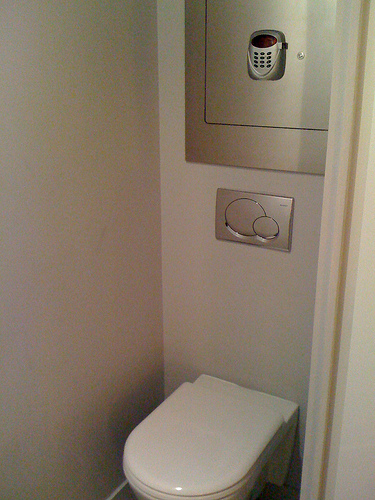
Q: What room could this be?
A: It is a bathroom.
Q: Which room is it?
A: It is a bathroom.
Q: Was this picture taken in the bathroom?
A: Yes, it was taken in the bathroom.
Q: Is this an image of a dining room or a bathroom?
A: It is showing a bathroom.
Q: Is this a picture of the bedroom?
A: No, the picture is showing the bathroom.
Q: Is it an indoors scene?
A: Yes, it is indoors.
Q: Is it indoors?
A: Yes, it is indoors.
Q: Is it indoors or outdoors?
A: It is indoors.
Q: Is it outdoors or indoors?
A: It is indoors.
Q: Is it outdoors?
A: No, it is indoors.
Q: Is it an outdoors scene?
A: No, it is indoors.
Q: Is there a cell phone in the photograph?
A: Yes, there is a cell phone.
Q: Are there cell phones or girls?
A: Yes, there is a cell phone.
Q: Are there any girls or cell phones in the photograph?
A: Yes, there is a cell phone.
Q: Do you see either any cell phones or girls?
A: Yes, there is a cell phone.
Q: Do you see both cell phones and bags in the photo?
A: No, there is a cell phone but no bags.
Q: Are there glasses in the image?
A: No, there are no glasses.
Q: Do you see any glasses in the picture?
A: No, there are no glasses.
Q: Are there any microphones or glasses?
A: No, there are no glasses or microphones.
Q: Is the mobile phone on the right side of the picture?
A: Yes, the mobile phone is on the right of the image.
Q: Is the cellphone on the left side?
A: No, the cellphone is on the right of the image.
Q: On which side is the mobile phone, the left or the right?
A: The mobile phone is on the right of the image.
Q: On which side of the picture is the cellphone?
A: The cellphone is on the right of the image.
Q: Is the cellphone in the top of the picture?
A: Yes, the cellphone is in the top of the image.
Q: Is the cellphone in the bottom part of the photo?
A: No, the cellphone is in the top of the image.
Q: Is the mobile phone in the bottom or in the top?
A: The mobile phone is in the top of the image.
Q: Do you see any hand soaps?
A: No, there are no hand soaps.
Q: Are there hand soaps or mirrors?
A: No, there are no hand soaps or mirrors.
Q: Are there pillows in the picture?
A: No, there are no pillows.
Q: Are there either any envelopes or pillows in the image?
A: No, there are no pillows or envelopes.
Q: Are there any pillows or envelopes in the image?
A: No, there are no pillows or envelopes.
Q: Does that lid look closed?
A: Yes, the lid is closed.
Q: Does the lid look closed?
A: Yes, the lid is closed.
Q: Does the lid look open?
A: No, the lid is closed.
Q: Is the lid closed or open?
A: The lid is closed.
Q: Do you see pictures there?
A: No, there are no pictures.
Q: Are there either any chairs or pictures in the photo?
A: No, there are no pictures or chairs.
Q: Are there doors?
A: Yes, there is a door.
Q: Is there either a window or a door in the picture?
A: Yes, there is a door.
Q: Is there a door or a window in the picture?
A: Yes, there is a door.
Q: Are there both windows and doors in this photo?
A: No, there is a door but no windows.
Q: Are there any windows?
A: No, there are no windows.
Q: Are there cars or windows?
A: No, there are no windows or cars.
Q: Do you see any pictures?
A: No, there are no pictures.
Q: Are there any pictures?
A: No, there are no pictures.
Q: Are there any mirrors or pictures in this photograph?
A: No, there are no pictures or mirrors.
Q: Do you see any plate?
A: Yes, there is a plate.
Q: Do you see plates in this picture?
A: Yes, there is a plate.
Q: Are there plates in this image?
A: Yes, there is a plate.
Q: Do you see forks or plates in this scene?
A: Yes, there is a plate.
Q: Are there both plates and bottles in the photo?
A: No, there is a plate but no bottles.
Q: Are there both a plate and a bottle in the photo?
A: No, there is a plate but no bottles.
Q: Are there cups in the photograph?
A: No, there are no cups.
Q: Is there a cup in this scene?
A: No, there are no cups.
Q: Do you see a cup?
A: No, there are no cups.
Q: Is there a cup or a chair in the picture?
A: No, there are no cups or chairs.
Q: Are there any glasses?
A: No, there are no glasses.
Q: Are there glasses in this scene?
A: No, there are no glasses.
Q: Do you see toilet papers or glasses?
A: No, there are no glasses or toilet papers.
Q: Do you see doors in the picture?
A: Yes, there is a door.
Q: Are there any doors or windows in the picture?
A: Yes, there is a door.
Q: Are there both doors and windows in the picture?
A: No, there is a door but no windows.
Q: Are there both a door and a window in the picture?
A: No, there is a door but no windows.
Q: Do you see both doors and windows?
A: No, there is a door but no windows.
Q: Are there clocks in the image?
A: No, there are no clocks.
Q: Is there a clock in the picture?
A: No, there are no clocks.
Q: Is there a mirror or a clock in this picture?
A: No, there are no clocks or mirrors.